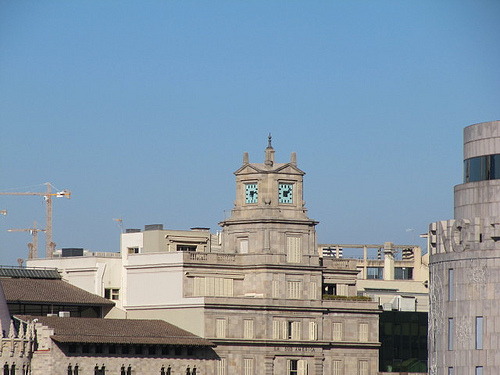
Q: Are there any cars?
A: No, there are no cars.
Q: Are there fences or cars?
A: No, there are no cars or fences.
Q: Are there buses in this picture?
A: No, there are no buses.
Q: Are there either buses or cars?
A: No, there are no buses or cars.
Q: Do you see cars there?
A: No, there are no cars.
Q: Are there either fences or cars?
A: No, there are no cars or fences.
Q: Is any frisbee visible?
A: No, there are no frisbees.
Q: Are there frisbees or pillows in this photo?
A: No, there are no frisbees or pillows.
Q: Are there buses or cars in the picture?
A: No, there are no cars or buses.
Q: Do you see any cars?
A: No, there are no cars.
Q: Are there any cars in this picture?
A: No, there are no cars.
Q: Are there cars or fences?
A: No, there are no cars or fences.